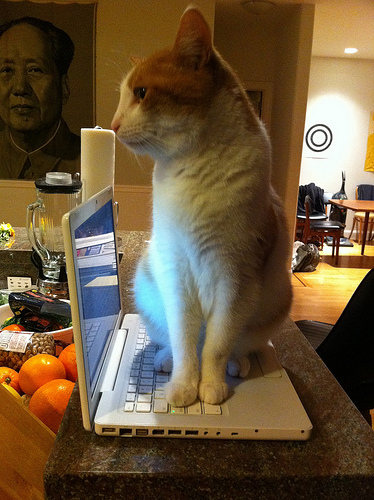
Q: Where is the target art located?
A: On a wall.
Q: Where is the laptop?
A: Counter.